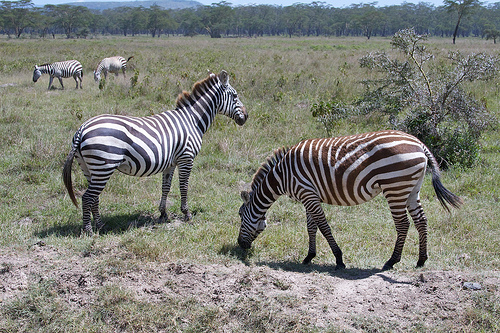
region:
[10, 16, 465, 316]
The zebras are in a field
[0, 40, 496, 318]
The zebras are male and female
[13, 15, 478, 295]
The zebras are looking for food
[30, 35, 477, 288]
The zebras are searching for water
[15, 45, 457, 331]
The zebras are looking for their mates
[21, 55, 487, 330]
The zebras are watching for danger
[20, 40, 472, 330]
The zebras are out in the open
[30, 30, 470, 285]
The zebras are having a great time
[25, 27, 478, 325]
The zebras are out in the sunshine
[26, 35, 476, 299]
The zebras are enjoying the day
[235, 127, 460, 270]
a zebra eating green grass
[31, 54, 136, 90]
two zebras in a grassland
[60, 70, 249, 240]
a zebra standing up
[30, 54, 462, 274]
four zebras standing in the grasslands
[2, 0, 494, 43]
trees next to a field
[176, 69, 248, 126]
the head of a zebra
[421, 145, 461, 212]
the tail of a zebra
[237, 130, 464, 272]
a stripped zebra eating grass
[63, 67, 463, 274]
two zebras standing by each other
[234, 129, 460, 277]
side view of a zebra eating grass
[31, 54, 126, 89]
Two zebras walking in the grass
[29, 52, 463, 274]
Four zebras in a field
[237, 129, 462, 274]
Brown and white striped zebra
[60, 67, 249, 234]
Black and white striped zebra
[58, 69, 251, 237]
Zebra standing in the grass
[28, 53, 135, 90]
Two zebras grazing on grass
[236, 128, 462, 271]
Zebra grazing on dry grass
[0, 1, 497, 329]
Safari scenery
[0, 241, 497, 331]
Mount of dirt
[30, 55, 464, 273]
Four zebras on a safari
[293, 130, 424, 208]
dirt on the zebra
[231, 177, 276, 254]
zebra is eating grass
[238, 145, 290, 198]
zebra's mane hair is black and white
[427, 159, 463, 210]
zebra's tail is swinging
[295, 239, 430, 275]
zebra's hooves are black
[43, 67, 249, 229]
zebra is standing still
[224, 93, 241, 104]
zebra's eye is black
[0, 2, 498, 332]
zebras standing in a field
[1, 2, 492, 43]
trees in the distance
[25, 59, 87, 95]
the zebra is eating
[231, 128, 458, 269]
a zebra is in a field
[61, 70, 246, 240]
a zebra is in a field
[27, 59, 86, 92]
a zebra is in a field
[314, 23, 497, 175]
a small flowering bush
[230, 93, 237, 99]
eye of a zebra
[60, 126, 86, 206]
tail of a zebra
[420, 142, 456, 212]
tail of a zebra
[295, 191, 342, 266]
legs of a zebra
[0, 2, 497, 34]
a line of trees in the distance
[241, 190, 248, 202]
ear ofa zebra